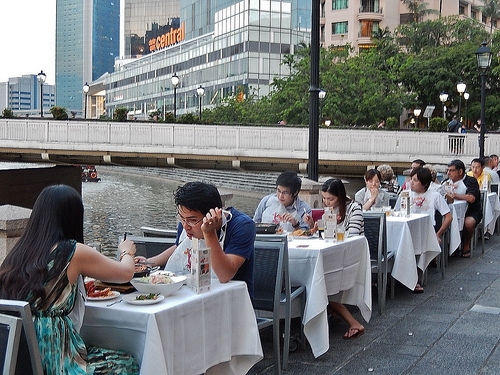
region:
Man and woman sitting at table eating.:
[0, 172, 242, 372]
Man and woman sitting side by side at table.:
[262, 160, 367, 317]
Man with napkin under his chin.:
[435, 157, 482, 242]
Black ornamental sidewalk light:
[460, 35, 495, 229]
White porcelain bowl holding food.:
[125, 266, 191, 298]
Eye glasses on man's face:
[173, 210, 203, 231]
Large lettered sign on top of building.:
[139, 22, 201, 54]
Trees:
[222, 24, 489, 126]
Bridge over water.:
[1, 112, 327, 232]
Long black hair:
[0, 183, 89, 328]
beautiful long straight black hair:
[1, 180, 111, 312]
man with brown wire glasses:
[160, 185, 235, 258]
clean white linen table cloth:
[85, 276, 244, 371]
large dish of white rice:
[113, 261, 195, 299]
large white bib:
[153, 230, 228, 295]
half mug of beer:
[307, 218, 373, 265]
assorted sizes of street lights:
[411, 44, 491, 126]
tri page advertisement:
[181, 241, 222, 308]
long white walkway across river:
[0, 108, 495, 163]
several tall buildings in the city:
[1, 2, 230, 114]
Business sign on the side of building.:
[146, 24, 183, 50]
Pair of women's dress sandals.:
[344, 325, 365, 340]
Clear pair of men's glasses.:
[172, 213, 205, 228]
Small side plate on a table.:
[128, 292, 167, 305]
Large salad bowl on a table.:
[130, 271, 190, 296]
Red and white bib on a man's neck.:
[445, 180, 467, 195]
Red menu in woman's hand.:
[310, 209, 323, 222]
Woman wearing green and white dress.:
[18, 245, 141, 373]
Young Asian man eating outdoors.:
[395, 170, 450, 291]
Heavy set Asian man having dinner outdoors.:
[256, 170, 308, 227]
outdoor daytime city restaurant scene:
[6, 0, 498, 361]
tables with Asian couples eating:
[10, 126, 496, 361]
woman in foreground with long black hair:
[5, 180, 145, 360]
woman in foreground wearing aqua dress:
[1, 177, 156, 367]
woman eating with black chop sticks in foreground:
[2, 175, 137, 370]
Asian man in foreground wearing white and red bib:
[140, 170, 265, 290]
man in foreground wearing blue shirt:
[130, 171, 256, 296]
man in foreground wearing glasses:
[131, 170, 268, 315]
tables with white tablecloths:
[81, 156, 496, 371]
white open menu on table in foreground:
[189, 241, 213, 296]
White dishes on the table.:
[114, 257, 187, 327]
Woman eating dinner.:
[8, 172, 145, 374]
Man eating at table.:
[149, 168, 244, 313]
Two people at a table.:
[263, 130, 363, 345]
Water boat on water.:
[66, 145, 118, 190]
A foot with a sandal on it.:
[303, 290, 375, 366]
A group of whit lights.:
[391, 64, 494, 131]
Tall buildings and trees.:
[6, 0, 488, 140]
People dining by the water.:
[23, 122, 306, 372]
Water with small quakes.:
[76, 137, 186, 264]